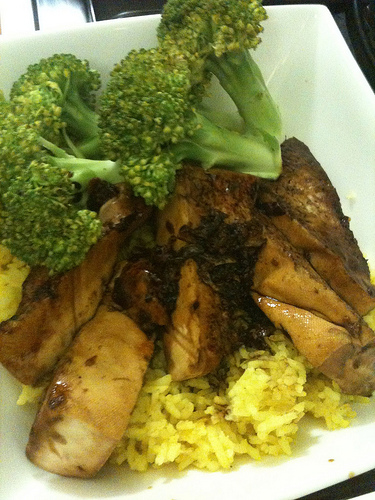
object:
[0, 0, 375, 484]
food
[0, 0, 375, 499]
plate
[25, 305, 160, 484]
chicken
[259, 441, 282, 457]
rice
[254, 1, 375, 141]
corner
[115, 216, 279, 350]
sauce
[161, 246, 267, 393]
chicken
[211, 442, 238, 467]
part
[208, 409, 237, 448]
some rice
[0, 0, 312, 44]
edge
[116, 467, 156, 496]
part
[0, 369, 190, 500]
shade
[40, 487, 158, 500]
edge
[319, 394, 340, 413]
rice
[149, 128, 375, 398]
meat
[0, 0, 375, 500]
sink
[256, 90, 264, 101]
spot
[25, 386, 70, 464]
dark area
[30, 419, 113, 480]
light area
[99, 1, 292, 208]
broccoli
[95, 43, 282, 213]
stalk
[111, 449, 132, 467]
rice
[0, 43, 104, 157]
broccoli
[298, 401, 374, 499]
part